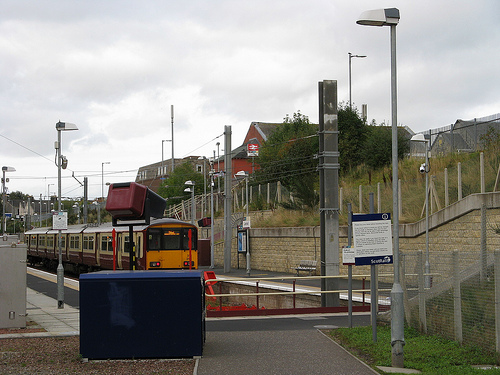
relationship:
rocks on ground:
[6, 345, 81, 373] [5, 337, 98, 374]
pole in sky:
[159, 104, 186, 163] [0, 5, 499, 130]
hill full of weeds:
[375, 145, 469, 197] [392, 142, 427, 189]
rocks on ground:
[0, 330, 196, 374] [2, 331, 194, 369]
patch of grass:
[317, 316, 498, 373] [330, 324, 495, 370]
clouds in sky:
[83, 20, 210, 88] [1, 0, 497, 201]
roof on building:
[209, 120, 415, 161] [242, 130, 313, 190]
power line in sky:
[0, 133, 57, 166] [1, 0, 497, 201]